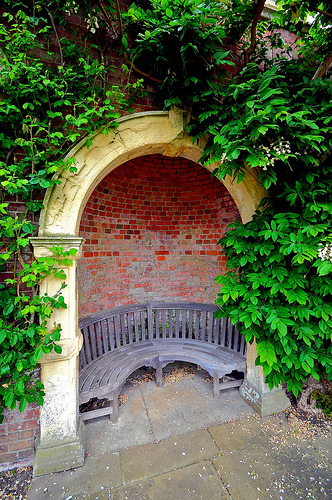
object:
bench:
[49, 302, 287, 424]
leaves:
[53, 344, 63, 357]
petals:
[2, 422, 331, 499]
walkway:
[0, 386, 330, 499]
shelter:
[25, 92, 309, 450]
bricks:
[110, 203, 123, 212]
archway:
[32, 105, 327, 442]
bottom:
[29, 358, 88, 473]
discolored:
[30, 113, 239, 272]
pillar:
[30, 161, 87, 474]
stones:
[214, 436, 331, 499]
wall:
[1, 9, 330, 443]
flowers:
[218, 149, 233, 165]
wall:
[79, 151, 248, 303]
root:
[290, 369, 331, 420]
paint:
[64, 117, 168, 176]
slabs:
[120, 425, 220, 487]